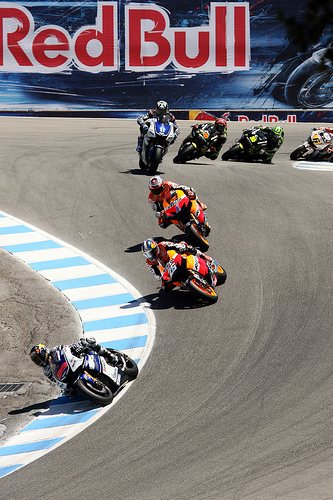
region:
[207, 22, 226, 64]
part of a letter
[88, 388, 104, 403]
part of a wheel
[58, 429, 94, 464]
part of a line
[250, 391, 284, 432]
part of a rioad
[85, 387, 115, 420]
part of a wheel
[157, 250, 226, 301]
red and orange motorcycle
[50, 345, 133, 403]
blue and white motorcycle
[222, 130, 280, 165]
black and yellow motorcycle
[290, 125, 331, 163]
white and yellow motorcycle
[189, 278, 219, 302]
red orange and black tire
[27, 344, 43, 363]
black and yellow tire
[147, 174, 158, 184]
white and orange helmet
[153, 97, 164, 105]
white and black helmet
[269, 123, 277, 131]
green and white helmet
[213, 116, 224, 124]
red and black helmet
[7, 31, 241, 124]
This is an ad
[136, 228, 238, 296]
This is a biker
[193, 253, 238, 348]
This is a bike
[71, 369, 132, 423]
This is a wheel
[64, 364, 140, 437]
The wheel is black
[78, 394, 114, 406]
This is a tire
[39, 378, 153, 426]
The tire is black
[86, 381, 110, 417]
The tire is rubber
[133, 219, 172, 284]
This is a helmet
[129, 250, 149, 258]
These are some glasses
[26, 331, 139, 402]
motorcycle and rider in first place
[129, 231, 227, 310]
motor cycle and rider in 2nd place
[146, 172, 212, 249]
motorcycle and rider in 3rd place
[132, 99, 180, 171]
motorcycle and rider in 4th place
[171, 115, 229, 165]
motorcycle and rider in 5th place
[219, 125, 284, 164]
motorcycle and rider in 6th place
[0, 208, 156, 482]
blue and white stripes on side of race track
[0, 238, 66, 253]
blue stripe on race track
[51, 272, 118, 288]
blue stripe on race track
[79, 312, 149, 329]
blue stripe on race track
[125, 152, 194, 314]
These are bikers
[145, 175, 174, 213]
This is a helmet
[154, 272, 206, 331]
This is a wheel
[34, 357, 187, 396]
There are two wheels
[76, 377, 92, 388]
This is a tire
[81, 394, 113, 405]
The tire is black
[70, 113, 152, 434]
This is a race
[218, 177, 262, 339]
These are scuffs on the track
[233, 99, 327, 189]
This is an ad